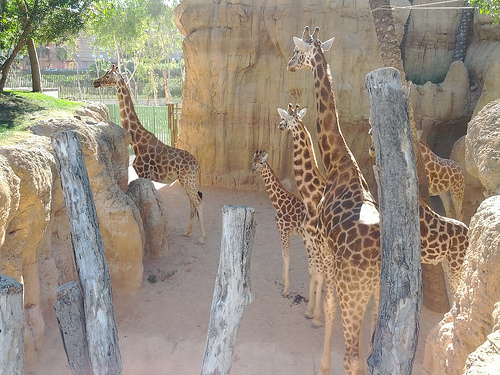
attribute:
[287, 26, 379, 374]
giraffe — enclosed, standing, black, patterned, shining, enclossed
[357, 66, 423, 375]
stump — tall, wooden, wood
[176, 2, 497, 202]
wall — rock, large, stone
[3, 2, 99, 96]
tree — leafy, green, tall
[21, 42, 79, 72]
building — behind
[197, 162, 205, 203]
tail — black